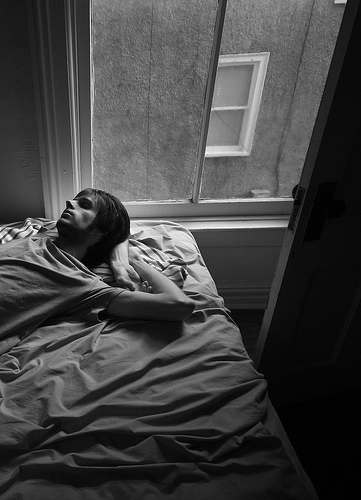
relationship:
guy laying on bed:
[1, 186, 201, 332] [1, 216, 320, 498]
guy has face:
[1, 186, 201, 332] [50, 187, 99, 229]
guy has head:
[1, 186, 201, 332] [53, 184, 129, 269]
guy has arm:
[1, 186, 201, 332] [93, 243, 198, 327]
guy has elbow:
[1, 186, 201, 332] [156, 280, 196, 327]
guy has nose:
[1, 186, 201, 332] [61, 195, 76, 208]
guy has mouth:
[1, 186, 201, 332] [58, 209, 75, 223]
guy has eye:
[1, 186, 201, 332] [76, 199, 92, 210]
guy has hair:
[1, 186, 201, 332] [76, 189, 131, 263]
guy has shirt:
[1, 186, 201, 332] [1, 232, 126, 364]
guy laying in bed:
[1, 186, 201, 332] [1, 216, 320, 498]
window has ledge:
[72, 3, 347, 218] [127, 199, 295, 238]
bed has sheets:
[1, 216, 320, 498] [3, 216, 305, 497]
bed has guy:
[1, 216, 320, 498] [1, 186, 201, 332]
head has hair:
[53, 184, 129, 269] [76, 189, 131, 263]